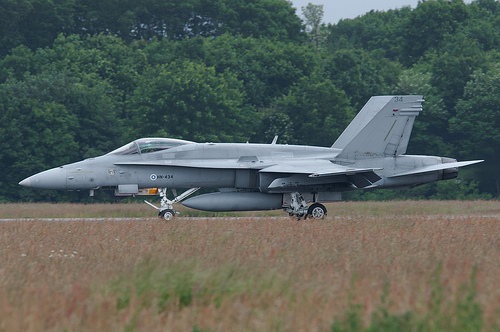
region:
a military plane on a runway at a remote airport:
[12, 75, 496, 218]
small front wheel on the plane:
[156, 209, 175, 219]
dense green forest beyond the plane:
[9, 6, 314, 122]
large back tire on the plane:
[301, 200, 333, 221]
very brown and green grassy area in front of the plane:
[85, 227, 403, 305]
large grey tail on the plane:
[333, 89, 438, 151]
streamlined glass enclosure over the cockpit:
[106, 130, 196, 157]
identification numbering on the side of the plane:
[147, 170, 177, 182]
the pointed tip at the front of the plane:
[12, 168, 37, 198]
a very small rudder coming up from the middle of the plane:
[266, 132, 283, 144]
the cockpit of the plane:
[110, 137, 194, 153]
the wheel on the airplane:
[308, 205, 325, 216]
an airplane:
[18, 90, 485, 218]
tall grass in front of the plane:
[14, 220, 489, 330]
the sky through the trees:
[288, 0, 416, 33]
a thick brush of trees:
[2, 0, 494, 125]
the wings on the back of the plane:
[344, 90, 417, 152]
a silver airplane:
[16, 90, 482, 223]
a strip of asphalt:
[8, 212, 496, 220]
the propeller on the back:
[419, 154, 484, 178]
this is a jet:
[45, 128, 499, 244]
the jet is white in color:
[198, 143, 239, 171]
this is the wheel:
[308, 195, 335, 225]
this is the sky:
[331, 2, 361, 15]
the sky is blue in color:
[326, 0, 343, 19]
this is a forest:
[1, 17, 356, 122]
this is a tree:
[451, 70, 498, 171]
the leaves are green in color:
[447, 34, 474, 69]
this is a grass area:
[268, 245, 385, 301]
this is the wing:
[316, 150, 362, 182]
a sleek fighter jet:
[13, 91, 471, 221]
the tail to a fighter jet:
[320, 89, 473, 191]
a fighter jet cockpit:
[107, 135, 200, 154]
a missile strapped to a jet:
[177, 192, 304, 214]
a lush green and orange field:
[7, 218, 497, 329]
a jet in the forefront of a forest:
[2, 13, 495, 198]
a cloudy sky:
[282, 0, 428, 36]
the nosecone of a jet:
[16, 160, 84, 191]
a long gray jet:
[14, 90, 490, 225]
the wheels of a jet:
[145, 180, 329, 220]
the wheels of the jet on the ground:
[147, 198, 333, 221]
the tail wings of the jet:
[334, 90, 429, 171]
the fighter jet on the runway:
[16, 86, 496, 221]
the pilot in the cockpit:
[143, 139, 157, 159]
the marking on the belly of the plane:
[145, 170, 179, 185]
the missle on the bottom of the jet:
[178, 185, 295, 214]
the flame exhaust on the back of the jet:
[438, 155, 460, 180]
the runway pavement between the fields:
[0, 213, 148, 221]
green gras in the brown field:
[70, 242, 492, 329]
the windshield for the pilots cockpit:
[110, 131, 194, 155]